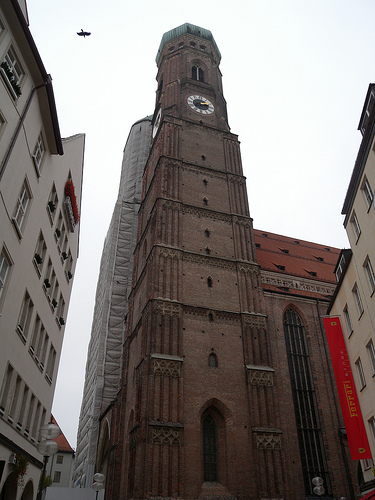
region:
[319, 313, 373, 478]
a red flag with yellow writing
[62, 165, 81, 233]
red flowers on a window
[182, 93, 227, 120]
clock on a tall building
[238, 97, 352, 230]
clear white sky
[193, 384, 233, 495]
window with an arch shape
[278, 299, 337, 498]
very tall gated window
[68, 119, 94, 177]
Pointy top of a building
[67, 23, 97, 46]
black bird flying in the sky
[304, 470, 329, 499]
two silver circles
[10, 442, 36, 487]
a green bush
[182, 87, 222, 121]
a clock on top of a tall church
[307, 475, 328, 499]
clear glass round shades over a street light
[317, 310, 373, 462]
a long red flag hanging from a building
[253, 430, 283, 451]
fanc carvings on the church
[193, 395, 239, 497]
an arched window on the church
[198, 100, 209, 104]
golden hands on the clock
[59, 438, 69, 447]
red terra cotta on the roof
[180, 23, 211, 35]
a large circular fence on top of the church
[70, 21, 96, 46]
a bird flying in the air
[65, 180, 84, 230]
a large red a sign on a building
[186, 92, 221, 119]
Clock on top of tower.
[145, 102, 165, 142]
Clock on side of tower.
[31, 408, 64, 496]
Street lights on left side of street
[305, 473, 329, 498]
Lights on right side of street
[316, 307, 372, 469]
Red banner hanging from building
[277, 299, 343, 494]
Old building has a large window on the sie.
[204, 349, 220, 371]
Tiny window on building.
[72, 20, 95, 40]
Bird flys over the buildings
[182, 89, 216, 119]
Clock displays roman numerals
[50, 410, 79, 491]
Home with red roof behind buildings.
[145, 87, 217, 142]
Two clocks on tower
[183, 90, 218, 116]
Clock is white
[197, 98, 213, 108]
Hands of clock are yellow.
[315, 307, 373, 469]
Red banner hanging from a building.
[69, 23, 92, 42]
Bird flying over a building.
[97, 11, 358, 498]
Old building is brown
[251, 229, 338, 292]
Building has red roof.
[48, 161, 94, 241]
Letters on front of building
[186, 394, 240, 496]
Arch windows on building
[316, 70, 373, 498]
Modern building next to old building.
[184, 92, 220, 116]
white clock on a tower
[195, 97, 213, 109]
gold hand on a clock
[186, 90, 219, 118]
black roman numerals on a clock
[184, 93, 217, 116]
roman numerals in a circle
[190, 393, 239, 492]
a deep arched window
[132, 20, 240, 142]
an octagonal top on the tower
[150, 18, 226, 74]
the tower roof is metal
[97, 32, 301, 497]
a brown brick tower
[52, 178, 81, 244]
red lettering on a white building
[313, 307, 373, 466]
a red banner